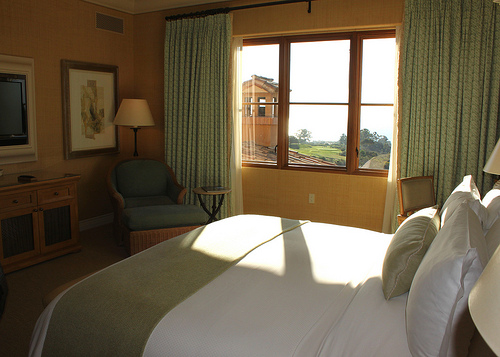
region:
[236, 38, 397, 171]
Hotel room window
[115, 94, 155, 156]
Lamp in the corner of hotel room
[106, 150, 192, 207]
Green chair in the corner of a hotel room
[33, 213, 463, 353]
White bed in a hotel room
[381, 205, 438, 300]
Light green pillow on a white bed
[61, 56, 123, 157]
Painting on the wall of a hotel room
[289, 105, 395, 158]
Green hilly landscape outside the window of a hotel room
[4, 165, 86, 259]
Wooden cabinet with two top drawers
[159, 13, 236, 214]
Light green window curtain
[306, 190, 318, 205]
Electrical plug-in on hotel room wall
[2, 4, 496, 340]
bedroom across from window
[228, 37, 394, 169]
sectional bedroom window with six panes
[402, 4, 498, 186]
light green window curtains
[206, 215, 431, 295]
green bedding matching the curtains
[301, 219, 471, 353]
most of the bedding is white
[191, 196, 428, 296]
light from window shining on the bed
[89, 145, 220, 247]
green and wood bedroom chair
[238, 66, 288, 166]
small structure visible outside window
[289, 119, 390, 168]
trees and grass visible outside window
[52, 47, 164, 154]
painting and lamp in bedroom corner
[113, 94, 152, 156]
lamp behind a chair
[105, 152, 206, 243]
chair and ottoman in the corner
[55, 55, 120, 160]
large framed picture on the wall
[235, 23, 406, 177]
open window with view of roof top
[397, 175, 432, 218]
chair by the window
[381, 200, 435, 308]
gray pillow on the bed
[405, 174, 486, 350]
white fluffy pillow on the bed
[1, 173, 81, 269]
dresser under a television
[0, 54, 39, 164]
television on the wall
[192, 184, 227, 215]
stool next to the chair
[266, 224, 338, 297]
shadow on the bed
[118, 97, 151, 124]
a lamp shade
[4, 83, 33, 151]
a television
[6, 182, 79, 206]
a dresser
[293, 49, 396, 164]
a window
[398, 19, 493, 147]
the curtains are green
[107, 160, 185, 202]
green chair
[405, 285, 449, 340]
a pillow is white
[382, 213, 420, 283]
a pillow on the bed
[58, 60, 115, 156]
a picture on the wall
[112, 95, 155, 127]
white lamp shade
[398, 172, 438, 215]
top of wooden and tan chair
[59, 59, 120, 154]
framed artwork on the wall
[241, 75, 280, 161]
structure seen through the window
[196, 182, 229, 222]
small round side table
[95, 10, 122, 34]
vent near the ceiling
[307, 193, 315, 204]
white power outlet under the window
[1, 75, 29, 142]
black television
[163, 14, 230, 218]
long dark green window curtain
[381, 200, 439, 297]
tan pillow on the bed